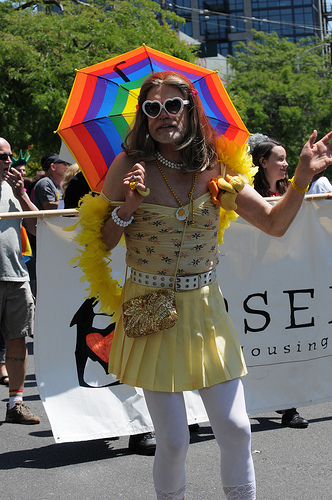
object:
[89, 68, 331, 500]
man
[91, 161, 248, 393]
dress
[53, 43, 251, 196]
umbrella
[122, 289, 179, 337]
purse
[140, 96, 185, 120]
sunglasses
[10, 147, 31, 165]
hat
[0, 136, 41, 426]
person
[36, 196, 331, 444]
banner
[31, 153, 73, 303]
person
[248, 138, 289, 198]
person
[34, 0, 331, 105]
building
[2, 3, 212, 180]
trees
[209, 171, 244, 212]
stuffed animal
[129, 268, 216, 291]
belt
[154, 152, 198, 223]
necklace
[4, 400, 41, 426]
tennis shoe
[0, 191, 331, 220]
pole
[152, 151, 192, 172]
bracelet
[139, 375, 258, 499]
leggings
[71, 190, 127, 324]
boa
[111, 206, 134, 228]
bracelet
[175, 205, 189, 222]
daisy pin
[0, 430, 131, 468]
shadow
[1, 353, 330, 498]
ground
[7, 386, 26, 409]
sock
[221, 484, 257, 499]
cuff